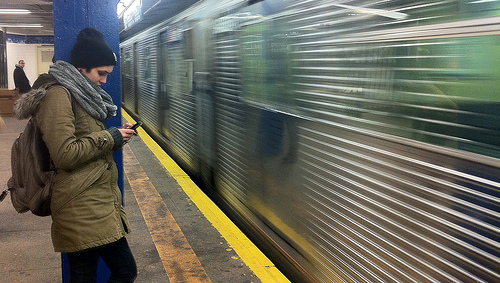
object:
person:
[5, 24, 142, 276]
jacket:
[19, 69, 132, 256]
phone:
[129, 120, 143, 129]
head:
[68, 27, 115, 88]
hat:
[70, 27, 116, 65]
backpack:
[0, 120, 57, 218]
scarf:
[48, 60, 120, 121]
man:
[14, 60, 32, 97]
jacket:
[13, 64, 33, 94]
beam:
[31, 27, 135, 281]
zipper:
[15, 136, 24, 189]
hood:
[13, 74, 60, 119]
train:
[105, 0, 500, 283]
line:
[122, 109, 299, 282]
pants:
[63, 238, 135, 282]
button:
[104, 138, 107, 141]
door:
[36, 44, 58, 78]